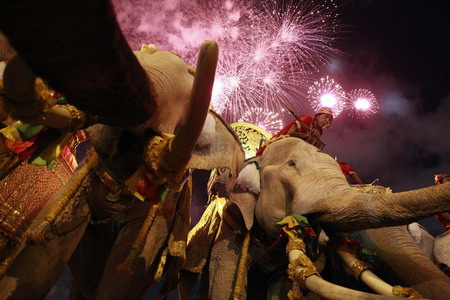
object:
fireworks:
[209, 0, 380, 137]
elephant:
[176, 134, 449, 299]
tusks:
[286, 239, 427, 299]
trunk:
[349, 181, 450, 231]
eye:
[285, 160, 298, 168]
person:
[254, 106, 333, 156]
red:
[296, 114, 310, 126]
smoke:
[116, 0, 209, 54]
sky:
[347, 0, 449, 80]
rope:
[229, 231, 252, 299]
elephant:
[0, 1, 245, 299]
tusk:
[154, 39, 219, 182]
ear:
[226, 156, 263, 229]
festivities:
[1, 0, 450, 298]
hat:
[313, 105, 334, 121]